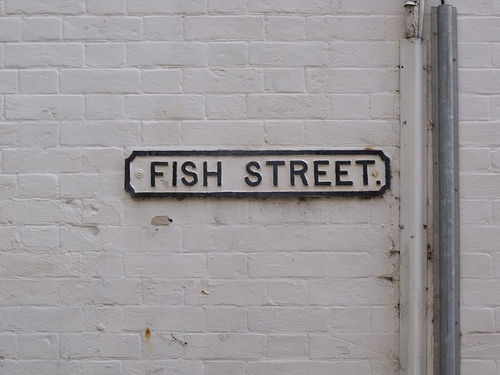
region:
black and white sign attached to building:
[107, 130, 395, 215]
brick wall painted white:
[67, 19, 253, 104]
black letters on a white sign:
[122, 142, 393, 206]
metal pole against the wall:
[429, 0, 468, 367]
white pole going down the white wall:
[394, 8, 428, 263]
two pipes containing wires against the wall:
[384, 3, 496, 353]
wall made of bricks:
[59, 33, 233, 122]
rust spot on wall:
[136, 311, 161, 350]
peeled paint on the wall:
[147, 209, 190, 243]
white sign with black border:
[116, 140, 396, 197]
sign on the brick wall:
[122, 145, 398, 227]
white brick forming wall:
[209, 279, 268, 302]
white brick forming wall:
[242, 308, 327, 332]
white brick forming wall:
[321, 281, 375, 303]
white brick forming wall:
[72, 276, 132, 308]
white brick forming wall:
[124, 229, 181, 254]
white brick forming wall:
[193, 339, 260, 357]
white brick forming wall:
[58, 331, 135, 349]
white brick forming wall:
[15, 253, 75, 277]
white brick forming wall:
[135, 45, 194, 61]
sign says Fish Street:
[85, 137, 481, 243]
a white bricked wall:
[10, 61, 64, 197]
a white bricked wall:
[92, 55, 343, 154]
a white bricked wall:
[94, 237, 329, 337]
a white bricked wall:
[461, 77, 498, 272]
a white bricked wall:
[51, 30, 235, 86]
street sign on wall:
[116, 140, 397, 210]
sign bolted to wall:
[116, 137, 401, 208]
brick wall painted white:
[3, 82, 415, 372]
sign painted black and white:
[118, 143, 395, 205]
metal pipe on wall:
[433, 3, 471, 373]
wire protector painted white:
[390, 5, 439, 373]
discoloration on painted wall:
[116, 313, 223, 360]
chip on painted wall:
[131, 205, 224, 236]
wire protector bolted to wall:
[380, 47, 442, 373]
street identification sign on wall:
[118, 143, 398, 202]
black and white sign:
[119, 117, 404, 234]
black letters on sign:
[143, 141, 402, 213]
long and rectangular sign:
[120, 147, 392, 213]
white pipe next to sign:
[370, 65, 433, 374]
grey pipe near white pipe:
[424, 2, 472, 357]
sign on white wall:
[122, 139, 394, 227]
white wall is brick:
[55, 222, 232, 332]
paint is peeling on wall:
[82, 207, 236, 346]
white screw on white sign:
[131, 166, 146, 190]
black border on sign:
[127, 145, 397, 220]